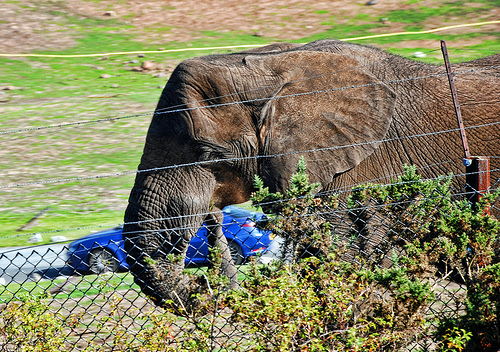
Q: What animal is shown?
A: A elephant.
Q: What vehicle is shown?
A: A car.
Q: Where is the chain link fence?
A: By the elephant.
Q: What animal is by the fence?
A: Elephant.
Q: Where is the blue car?
A: Behind the elephant.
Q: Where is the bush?
A: By the elephant.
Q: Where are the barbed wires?
A: Above the chain link fence.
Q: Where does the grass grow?
A: Across the road.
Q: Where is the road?
A: Under the car.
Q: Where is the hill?
A: Behind the car.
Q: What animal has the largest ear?
A: The elephant.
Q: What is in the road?
A: Car.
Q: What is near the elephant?
A: Fence.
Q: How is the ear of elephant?
A: Flat.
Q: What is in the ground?
A: Elephant.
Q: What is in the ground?
A: Animal.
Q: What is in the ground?
A: Fence.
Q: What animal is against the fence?
A: Elephant.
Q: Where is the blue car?
A: On the road.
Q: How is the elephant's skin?
A: Wrinkled.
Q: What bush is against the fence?
A: A green one.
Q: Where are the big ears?
A: On the elephant's head.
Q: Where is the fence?
A: In front of the eiephant.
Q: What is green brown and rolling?
A: The hills.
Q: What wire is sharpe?
A: Barbed.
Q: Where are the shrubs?
A: On the fence.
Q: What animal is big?
A: Elephant.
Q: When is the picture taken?
A: Daytime.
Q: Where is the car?
A: On the road.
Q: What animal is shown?
A: An elephant.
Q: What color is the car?
A: Blue.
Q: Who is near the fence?
A: The elephant.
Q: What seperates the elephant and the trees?
A: A fence.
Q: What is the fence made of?
A: Metal and wire.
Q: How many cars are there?
A: One.